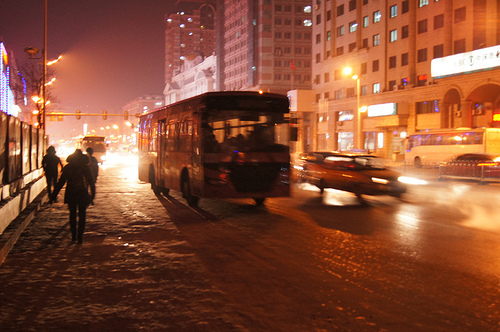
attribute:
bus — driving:
[138, 87, 300, 206]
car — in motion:
[301, 148, 408, 206]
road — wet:
[0, 152, 499, 327]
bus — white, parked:
[396, 128, 499, 171]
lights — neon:
[1, 40, 28, 119]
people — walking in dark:
[41, 144, 100, 243]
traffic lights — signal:
[74, 110, 130, 121]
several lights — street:
[341, 39, 498, 125]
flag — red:
[288, 58, 299, 90]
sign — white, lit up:
[432, 42, 499, 82]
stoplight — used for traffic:
[72, 110, 84, 121]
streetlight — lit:
[340, 65, 367, 152]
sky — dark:
[1, 1, 205, 133]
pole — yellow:
[350, 72, 366, 150]